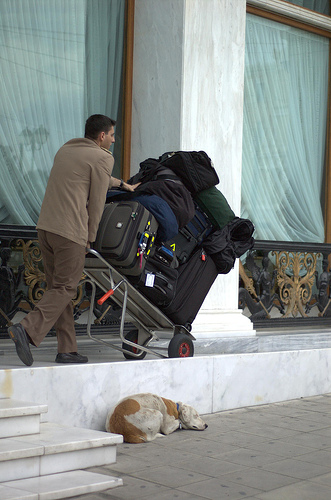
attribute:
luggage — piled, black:
[97, 148, 254, 326]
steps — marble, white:
[9, 395, 133, 499]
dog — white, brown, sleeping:
[104, 389, 207, 443]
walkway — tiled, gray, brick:
[107, 393, 330, 498]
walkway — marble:
[1, 336, 329, 375]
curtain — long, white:
[3, 1, 330, 244]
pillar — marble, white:
[137, 0, 255, 341]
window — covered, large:
[2, 3, 330, 312]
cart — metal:
[91, 238, 195, 358]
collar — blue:
[174, 400, 187, 431]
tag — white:
[140, 270, 159, 290]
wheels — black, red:
[123, 326, 191, 362]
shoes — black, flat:
[9, 320, 88, 373]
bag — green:
[193, 181, 237, 232]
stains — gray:
[126, 406, 311, 498]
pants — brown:
[26, 231, 92, 356]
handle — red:
[92, 287, 114, 306]